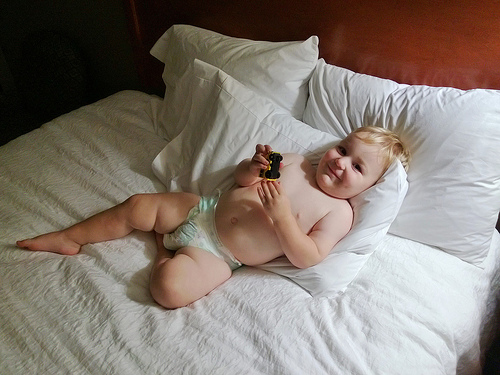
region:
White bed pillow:
[150, 21, 320, 143]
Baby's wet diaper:
[161, 188, 241, 274]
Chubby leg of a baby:
[75, 189, 204, 247]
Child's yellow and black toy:
[262, 150, 284, 181]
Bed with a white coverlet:
[2, 86, 499, 373]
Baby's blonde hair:
[350, 124, 412, 172]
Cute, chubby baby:
[14, 122, 409, 311]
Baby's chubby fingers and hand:
[255, 175, 287, 220]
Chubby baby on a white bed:
[0, 85, 495, 370]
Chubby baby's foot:
[11, 230, 81, 256]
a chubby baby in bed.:
[9, 125, 414, 312]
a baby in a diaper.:
[147, 165, 232, 317]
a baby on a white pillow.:
[135, 50, 414, 297]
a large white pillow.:
[284, 38, 495, 278]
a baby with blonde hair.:
[303, 125, 410, 216]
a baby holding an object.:
[220, 145, 311, 234]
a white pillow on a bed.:
[106, 3, 321, 143]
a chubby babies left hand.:
[249, 178, 312, 245]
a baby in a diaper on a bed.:
[155, 185, 240, 297]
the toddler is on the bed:
[12, 113, 437, 343]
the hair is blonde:
[365, 121, 399, 156]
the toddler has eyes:
[337, 138, 369, 183]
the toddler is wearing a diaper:
[161, 190, 241, 272]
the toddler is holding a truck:
[255, 141, 285, 186]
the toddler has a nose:
[330, 154, 346, 172]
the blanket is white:
[12, 298, 106, 360]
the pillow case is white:
[436, 116, 498, 201]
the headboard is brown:
[353, 17, 478, 57]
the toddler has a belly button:
[222, 207, 251, 237]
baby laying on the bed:
[24, 112, 370, 319]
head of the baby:
[308, 123, 391, 201]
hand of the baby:
[247, 179, 299, 236]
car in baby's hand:
[258, 150, 283, 185]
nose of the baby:
[331, 157, 343, 175]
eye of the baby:
[348, 158, 373, 176]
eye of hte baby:
[332, 140, 349, 155]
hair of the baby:
[345, 125, 404, 151]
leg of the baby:
[11, 219, 151, 265]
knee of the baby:
[120, 260, 205, 340]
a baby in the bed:
[2, 89, 429, 303]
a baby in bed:
[51, 103, 428, 290]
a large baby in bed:
[16, 98, 422, 304]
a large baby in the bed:
[23, 93, 425, 340]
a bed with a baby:
[42, 105, 442, 350]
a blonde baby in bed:
[47, 81, 414, 314]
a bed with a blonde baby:
[4, 77, 485, 330]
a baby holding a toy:
[159, 103, 457, 285]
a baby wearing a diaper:
[39, 43, 383, 323]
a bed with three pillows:
[119, 11, 489, 261]